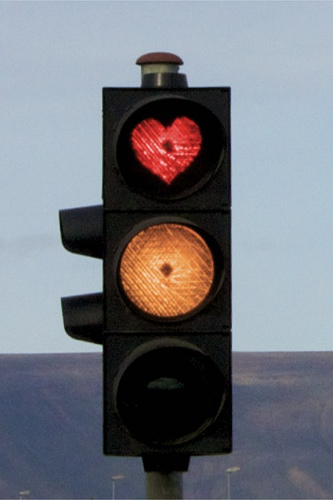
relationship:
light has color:
[74, 35, 258, 482] [97, 73, 236, 208]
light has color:
[74, 35, 258, 482] [101, 193, 233, 325]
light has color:
[74, 35, 258, 482] [85, 322, 234, 458]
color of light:
[109, 90, 230, 203] [55, 42, 291, 467]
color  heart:
[109, 90, 230, 203] [131, 116, 201, 186]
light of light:
[89, 330, 247, 460] [28, 30, 296, 491]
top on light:
[109, 41, 194, 83] [39, 47, 307, 477]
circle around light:
[97, 83, 232, 208] [105, 88, 233, 209]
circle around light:
[111, 214, 227, 324] [106, 204, 228, 325]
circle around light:
[106, 332, 241, 462] [109, 332, 231, 446]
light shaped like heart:
[98, 89, 236, 205] [117, 108, 206, 190]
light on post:
[60, 47, 234, 470] [114, 462, 198, 498]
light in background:
[215, 454, 246, 496] [15, 316, 312, 496]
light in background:
[88, 468, 148, 498] [15, 316, 312, 496]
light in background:
[12, 477, 33, 498] [15, 316, 312, 496]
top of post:
[84, 44, 233, 108] [127, 59, 189, 83]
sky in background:
[8, 8, 317, 192] [12, 6, 321, 246]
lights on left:
[43, 179, 119, 360] [20, 76, 125, 498]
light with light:
[60, 47, 234, 470] [89, 82, 238, 204]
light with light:
[60, 47, 234, 470] [99, 201, 242, 329]